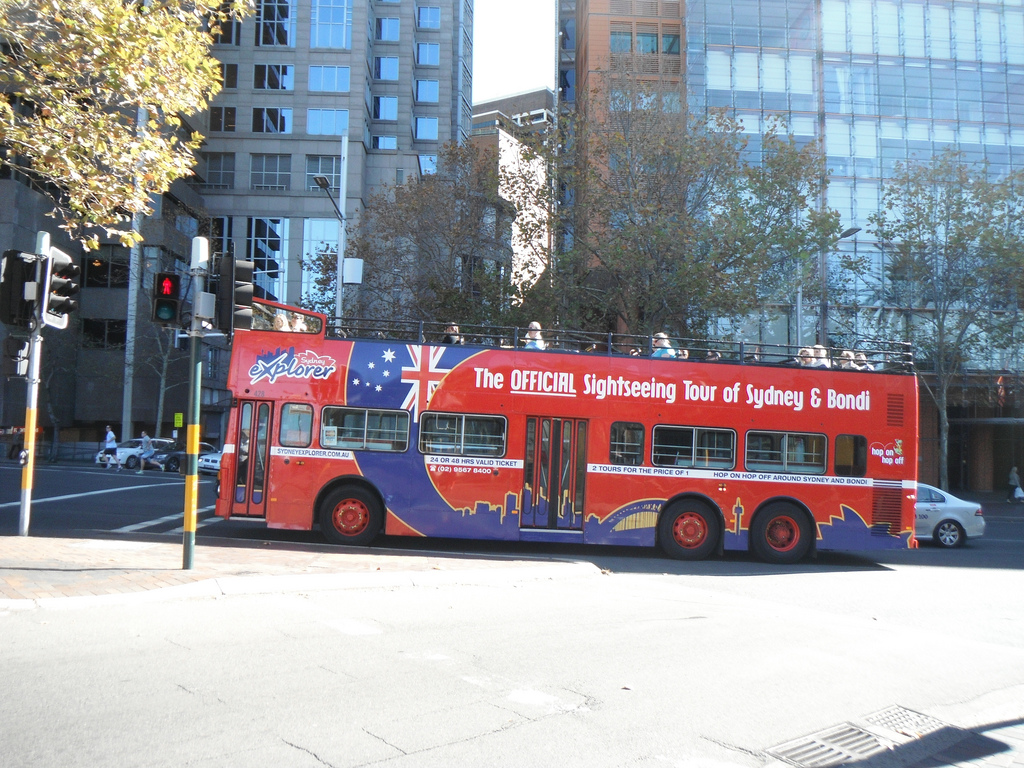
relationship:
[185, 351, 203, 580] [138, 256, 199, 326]
post with traffic light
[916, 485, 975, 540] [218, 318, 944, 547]
car behind bus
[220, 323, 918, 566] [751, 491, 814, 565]
bus with wheel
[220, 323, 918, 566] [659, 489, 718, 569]
bus with wheel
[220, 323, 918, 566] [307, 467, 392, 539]
bus with wheel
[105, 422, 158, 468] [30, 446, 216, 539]
people walking across street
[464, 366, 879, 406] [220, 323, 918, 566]
writing on side of bus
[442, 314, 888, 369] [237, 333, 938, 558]
people on top of bus